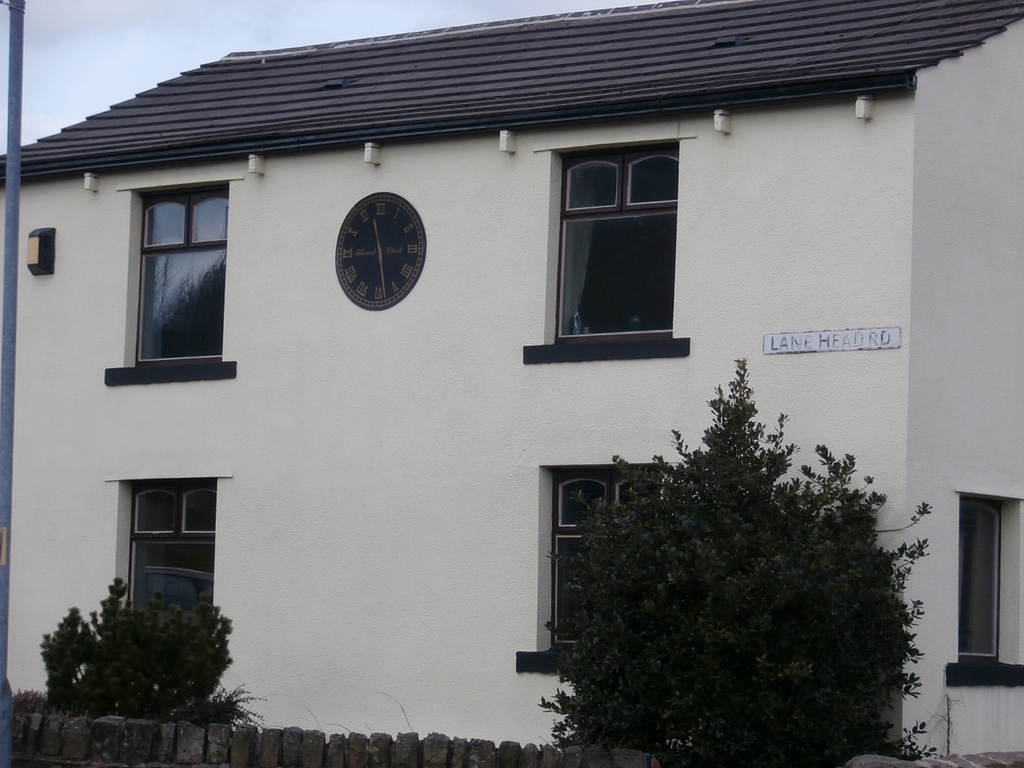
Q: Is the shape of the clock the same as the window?
A: No, the clock is round and the window is square.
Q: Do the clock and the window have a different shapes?
A: Yes, the clock is round and the window is square.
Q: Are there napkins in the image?
A: No, there are no napkins.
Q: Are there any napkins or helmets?
A: No, there are no napkins or helmets.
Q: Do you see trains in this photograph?
A: No, there are no trains.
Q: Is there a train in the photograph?
A: No, there are no trains.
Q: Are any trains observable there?
A: No, there are no trains.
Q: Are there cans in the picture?
A: No, there are no cans.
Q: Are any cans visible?
A: No, there are no cans.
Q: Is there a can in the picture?
A: No, there are no cans.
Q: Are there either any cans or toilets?
A: No, there are no cans or toilets.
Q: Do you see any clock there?
A: Yes, there is a clock.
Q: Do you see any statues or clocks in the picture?
A: Yes, there is a clock.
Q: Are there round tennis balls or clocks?
A: Yes, there is a round clock.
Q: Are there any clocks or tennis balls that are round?
A: Yes, the clock is round.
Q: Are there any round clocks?
A: Yes, there is a round clock.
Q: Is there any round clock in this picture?
A: Yes, there is a round clock.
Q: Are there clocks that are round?
A: Yes, there is a clock that is round.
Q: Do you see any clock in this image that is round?
A: Yes, there is a clock that is round.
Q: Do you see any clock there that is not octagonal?
A: Yes, there is an round clock.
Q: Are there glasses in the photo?
A: No, there are no glasses.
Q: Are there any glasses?
A: No, there are no glasses.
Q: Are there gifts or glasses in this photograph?
A: No, there are no glasses or gifts.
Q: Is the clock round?
A: Yes, the clock is round.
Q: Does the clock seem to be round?
A: Yes, the clock is round.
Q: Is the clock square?
A: No, the clock is round.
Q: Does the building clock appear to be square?
A: No, the clock is round.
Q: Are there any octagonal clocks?
A: No, there is a clock but it is round.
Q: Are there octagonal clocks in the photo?
A: No, there is a clock but it is round.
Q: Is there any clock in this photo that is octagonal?
A: No, there is a clock but it is round.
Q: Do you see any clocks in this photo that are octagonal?
A: No, there is a clock but it is round.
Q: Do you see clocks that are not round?
A: No, there is a clock but it is round.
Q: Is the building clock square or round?
A: The clock is round.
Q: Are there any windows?
A: Yes, there is a window.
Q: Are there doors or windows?
A: Yes, there is a window.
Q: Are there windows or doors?
A: Yes, there is a window.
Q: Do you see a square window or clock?
A: Yes, there is a square window.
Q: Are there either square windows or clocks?
A: Yes, there is a square window.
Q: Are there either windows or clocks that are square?
A: Yes, the window is square.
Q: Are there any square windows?
A: Yes, there is a square window.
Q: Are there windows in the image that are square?
A: Yes, there is a square window.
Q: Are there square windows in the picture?
A: Yes, there is a square window.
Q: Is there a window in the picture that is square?
A: Yes, there is a window that is square.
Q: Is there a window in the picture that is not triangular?
A: Yes, there is a square window.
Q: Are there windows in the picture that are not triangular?
A: Yes, there is a square window.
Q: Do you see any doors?
A: No, there are no doors.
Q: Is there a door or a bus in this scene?
A: No, there are no doors or buses.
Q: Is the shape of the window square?
A: Yes, the window is square.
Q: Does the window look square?
A: Yes, the window is square.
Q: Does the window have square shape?
A: Yes, the window is square.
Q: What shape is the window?
A: The window is square.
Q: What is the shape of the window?
A: The window is square.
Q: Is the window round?
A: No, the window is square.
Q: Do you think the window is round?
A: No, the window is square.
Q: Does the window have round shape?
A: No, the window is square.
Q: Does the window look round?
A: No, the window is square.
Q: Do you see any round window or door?
A: No, there is a window but it is square.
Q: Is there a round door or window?
A: No, there is a window but it is square.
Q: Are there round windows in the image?
A: No, there is a window but it is square.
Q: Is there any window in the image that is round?
A: No, there is a window but it is square.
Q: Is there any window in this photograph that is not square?
A: No, there is a window but it is square.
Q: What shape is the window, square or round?
A: The window is square.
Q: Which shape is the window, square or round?
A: The window is square.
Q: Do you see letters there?
A: Yes, there are letters.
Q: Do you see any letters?
A: Yes, there are letters.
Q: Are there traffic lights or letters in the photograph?
A: Yes, there are letters.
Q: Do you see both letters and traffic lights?
A: No, there are letters but no traffic lights.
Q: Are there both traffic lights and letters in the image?
A: No, there are letters but no traffic lights.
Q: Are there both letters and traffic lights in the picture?
A: No, there are letters but no traffic lights.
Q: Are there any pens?
A: No, there are no pens.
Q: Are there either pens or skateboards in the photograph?
A: No, there are no pens or skateboards.